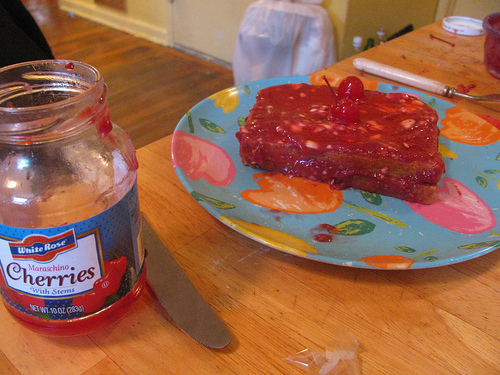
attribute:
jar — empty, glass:
[14, 44, 140, 333]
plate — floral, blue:
[170, 64, 492, 278]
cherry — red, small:
[341, 72, 361, 96]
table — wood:
[43, 30, 473, 334]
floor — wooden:
[29, 27, 216, 143]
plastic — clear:
[232, 6, 329, 76]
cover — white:
[448, 11, 488, 39]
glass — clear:
[8, 73, 123, 206]